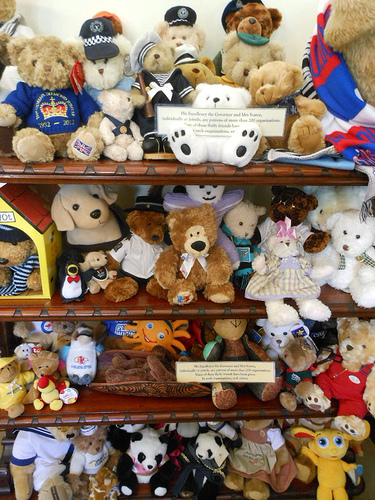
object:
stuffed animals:
[73, 17, 145, 164]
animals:
[76, 8, 146, 163]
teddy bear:
[153, 200, 237, 309]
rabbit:
[246, 219, 332, 324]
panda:
[121, 424, 173, 497]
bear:
[302, 208, 374, 291]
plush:
[273, 420, 338, 500]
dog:
[50, 183, 123, 248]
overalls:
[313, 362, 375, 419]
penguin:
[54, 243, 94, 307]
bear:
[184, 425, 233, 499]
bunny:
[294, 425, 363, 499]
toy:
[0, 33, 106, 166]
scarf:
[307, 2, 366, 122]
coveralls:
[306, 350, 374, 420]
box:
[0, 198, 64, 301]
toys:
[247, 57, 326, 160]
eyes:
[316, 435, 329, 447]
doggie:
[50, 184, 123, 249]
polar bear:
[155, 79, 289, 168]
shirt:
[1, 80, 103, 134]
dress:
[129, 69, 196, 106]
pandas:
[191, 429, 230, 499]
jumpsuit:
[313, 355, 373, 416]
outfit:
[0, 80, 103, 134]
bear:
[0, 31, 116, 164]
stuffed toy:
[69, 425, 112, 500]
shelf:
[0, 157, 372, 193]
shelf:
[0, 292, 375, 321]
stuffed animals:
[306, 185, 374, 301]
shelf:
[0, 379, 370, 432]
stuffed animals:
[1, 353, 36, 423]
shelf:
[1, 473, 374, 499]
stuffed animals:
[184, 419, 231, 496]